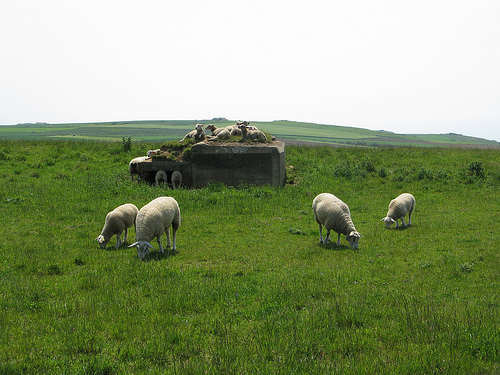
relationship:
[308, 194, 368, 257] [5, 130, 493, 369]
sheep in field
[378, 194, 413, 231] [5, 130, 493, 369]
sheep in field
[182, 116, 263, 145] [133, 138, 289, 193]
sheep on top of structure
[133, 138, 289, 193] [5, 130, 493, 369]
structure in field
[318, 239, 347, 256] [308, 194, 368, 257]
shadow cast by sheep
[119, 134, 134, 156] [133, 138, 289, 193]
plant near structure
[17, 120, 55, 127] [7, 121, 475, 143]
trees on hill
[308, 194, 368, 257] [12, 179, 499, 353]
sheep on grass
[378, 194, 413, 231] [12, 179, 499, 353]
sheep on grass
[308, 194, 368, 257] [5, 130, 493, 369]
sheep in a field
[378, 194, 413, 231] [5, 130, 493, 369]
sheep in a field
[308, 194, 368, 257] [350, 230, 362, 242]
sheep has two ears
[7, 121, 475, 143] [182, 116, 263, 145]
hill behind sheep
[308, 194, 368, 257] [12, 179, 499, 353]
sheep in grass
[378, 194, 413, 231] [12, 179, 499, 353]
sheep in grass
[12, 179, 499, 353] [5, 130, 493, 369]
grass in a field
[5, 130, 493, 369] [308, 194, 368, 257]
field full of sheep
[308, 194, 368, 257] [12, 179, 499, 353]
sheep eating grass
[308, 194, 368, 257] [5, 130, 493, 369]
sheep eating in field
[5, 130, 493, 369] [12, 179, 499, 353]
field of grass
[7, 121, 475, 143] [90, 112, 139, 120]
hill in distance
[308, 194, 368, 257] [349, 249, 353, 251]
sheep has head down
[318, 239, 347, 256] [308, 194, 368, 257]
shadow from a sheep